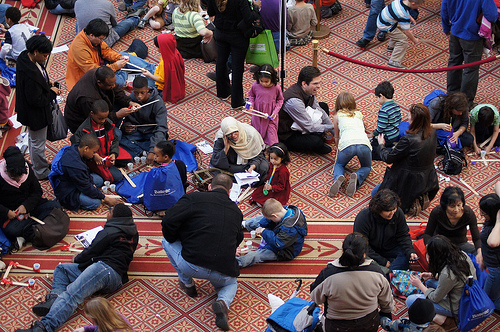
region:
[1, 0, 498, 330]
People sitting on a floor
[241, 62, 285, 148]
Girl wearing a pink dress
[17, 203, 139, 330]
Man in black jacket laying on the floor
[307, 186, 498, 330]
Five women sitting in a group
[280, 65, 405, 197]
Man laughing with two children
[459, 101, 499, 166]
Boy making something on the floor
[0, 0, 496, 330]
People constructing items with sticks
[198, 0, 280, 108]
Woman carrying a green bag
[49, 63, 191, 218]
Family of five sitting in a group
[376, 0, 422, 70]
Boy wearing a striped shirt and khaki pants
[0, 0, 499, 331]
group of people gathered together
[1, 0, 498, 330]
group of people sitting on the ground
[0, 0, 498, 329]
people divided into smaller groups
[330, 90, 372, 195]
little girl in white shirt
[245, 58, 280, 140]
little girl in pink dress standing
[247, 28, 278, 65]
large green shopping bag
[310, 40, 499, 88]
red VIP rope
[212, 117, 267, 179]
woman in a white head wrap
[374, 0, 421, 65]
little boy in a white and blue stripe shirt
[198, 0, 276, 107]
woman holding green shopping bag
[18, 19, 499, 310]
lots of people sitting on the floor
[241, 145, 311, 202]
a little girl in red dress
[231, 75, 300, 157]
a little girl in pink dress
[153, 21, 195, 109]
a red jacket hanging from head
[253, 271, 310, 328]
top of a blue stroller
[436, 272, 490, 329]
blue backpack on back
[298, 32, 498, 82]
a red rope for line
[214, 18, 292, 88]
a green and white bag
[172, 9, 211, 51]
a green and white striped shirt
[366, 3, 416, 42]
a blue white and black striped shirt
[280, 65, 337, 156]
A man sitting down.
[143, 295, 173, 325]
Part of the ground.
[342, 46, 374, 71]
Part of a red rope.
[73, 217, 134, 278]
A black hooded jacket.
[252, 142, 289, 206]
A little girl sitting down.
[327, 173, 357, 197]
The bottom of the girl's shoes.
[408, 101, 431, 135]
The woman's brown hair.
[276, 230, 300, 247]
Part of a blue and black jacket.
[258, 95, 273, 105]
Part of a purple dress.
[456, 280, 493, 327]
A blue backpack.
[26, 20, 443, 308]
people are on tiled floor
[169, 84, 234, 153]
tiled floor is red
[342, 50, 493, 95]
red rope near people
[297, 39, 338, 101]
gold barrier near people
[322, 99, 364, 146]
girl has white shirt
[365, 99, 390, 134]
boy has blue striped shirt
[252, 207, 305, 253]
boy has blue and black coat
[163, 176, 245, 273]
man has black coat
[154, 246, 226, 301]
man has blue jeans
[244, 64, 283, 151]
girl has lavender dress